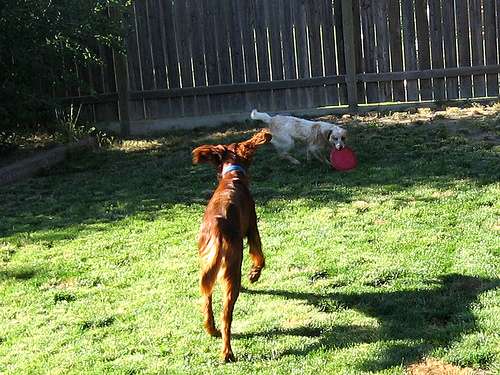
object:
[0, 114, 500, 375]
grass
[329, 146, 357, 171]
frisbee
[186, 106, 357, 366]
two dogs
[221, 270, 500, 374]
shadow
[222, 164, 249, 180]
collar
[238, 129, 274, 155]
ears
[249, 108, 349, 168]
dog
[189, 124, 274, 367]
dog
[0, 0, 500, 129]
fence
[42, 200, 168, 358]
lawn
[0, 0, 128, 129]
tree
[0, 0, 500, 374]
yard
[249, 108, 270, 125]
tail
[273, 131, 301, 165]
hind leg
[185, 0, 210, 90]
boards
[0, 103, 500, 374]
ground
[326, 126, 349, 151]
head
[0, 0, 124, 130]
background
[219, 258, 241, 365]
back legs